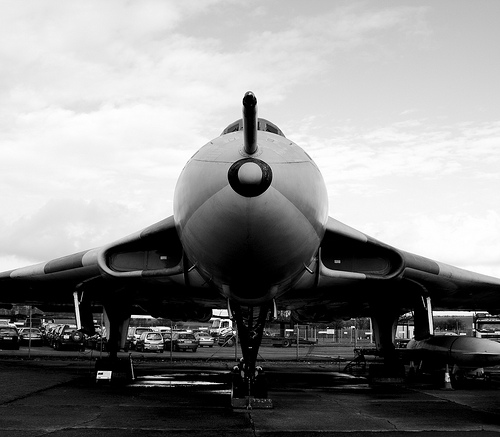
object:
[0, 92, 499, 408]
plane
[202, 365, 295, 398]
wheels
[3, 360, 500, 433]
ground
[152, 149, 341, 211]
white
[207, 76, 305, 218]
sharphead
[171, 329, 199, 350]
cars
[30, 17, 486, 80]
sky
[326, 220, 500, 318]
planeswing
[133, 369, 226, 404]
fllor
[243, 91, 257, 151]
nose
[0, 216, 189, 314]
leftarm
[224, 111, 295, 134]
windows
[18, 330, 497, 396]
dockingstation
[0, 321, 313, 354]
parkinglot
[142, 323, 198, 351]
vehicles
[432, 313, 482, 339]
frontview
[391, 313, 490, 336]
schoolbus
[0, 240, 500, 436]
airport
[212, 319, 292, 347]
largetruck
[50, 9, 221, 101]
cumulusclouds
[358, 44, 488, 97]
sky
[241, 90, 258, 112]
fronttip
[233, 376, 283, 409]
airplanewheel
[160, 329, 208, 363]
linkfence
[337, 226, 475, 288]
wing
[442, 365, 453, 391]
cone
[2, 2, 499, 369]
black and white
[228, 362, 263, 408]
gear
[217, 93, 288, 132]
cockpitarea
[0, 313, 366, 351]
background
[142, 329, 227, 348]
car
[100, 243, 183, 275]
propeller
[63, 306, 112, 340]
wings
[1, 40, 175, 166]
clouds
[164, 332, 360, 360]
fence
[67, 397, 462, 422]
tarmac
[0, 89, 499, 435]
airplaine